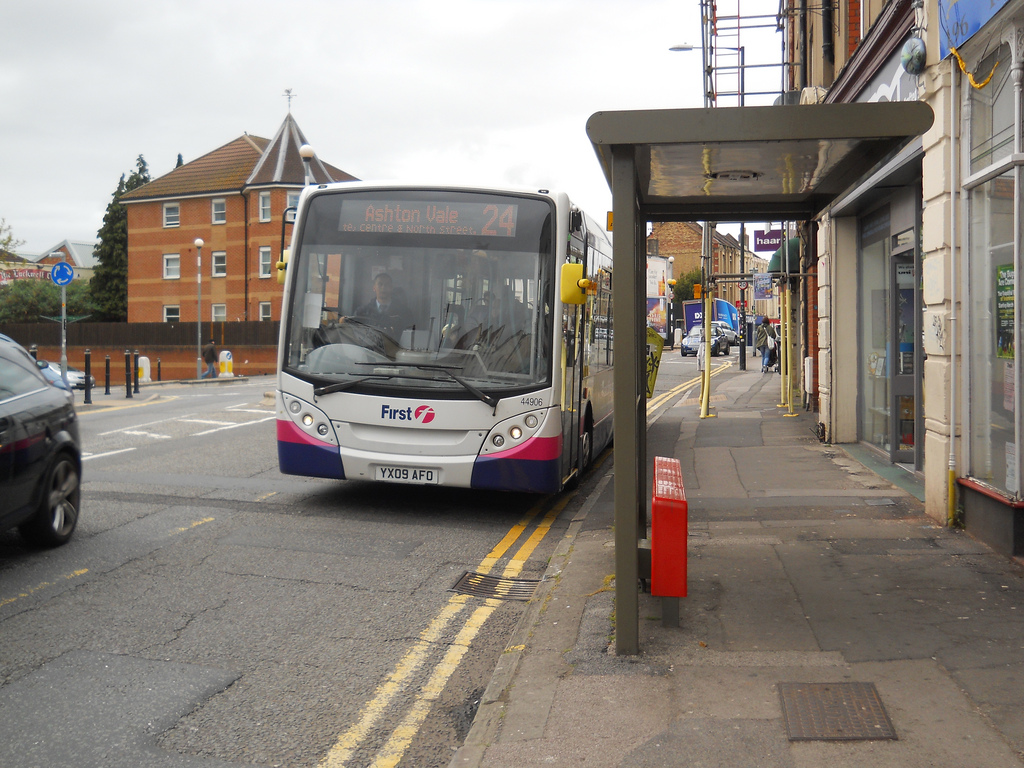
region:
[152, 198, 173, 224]
a window on a building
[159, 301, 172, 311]
a window on a building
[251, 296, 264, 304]
a window on a building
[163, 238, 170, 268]
a window on a building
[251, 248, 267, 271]
a window on a building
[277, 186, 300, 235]
a window on a building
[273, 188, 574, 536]
the front of a bus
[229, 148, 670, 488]
a large white bus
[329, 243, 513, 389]
the windshield of a bus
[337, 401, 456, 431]
the logo of a bus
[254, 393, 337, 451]
the right headlight of a bus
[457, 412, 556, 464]
the left headlight of a bus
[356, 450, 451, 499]
the license plate of a bus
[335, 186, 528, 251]
the sign on a bus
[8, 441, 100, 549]
the wheel of a car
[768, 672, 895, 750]
Sewer drain opening on the sidewalk.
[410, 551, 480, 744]
Two solid yellow lines on the ground.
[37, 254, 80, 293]
Blue sign on top of the pole.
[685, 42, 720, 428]
Yellow pole on the side of the building.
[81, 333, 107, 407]
Small black pole in the parking lot.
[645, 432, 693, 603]
Red banister on the side of bus stop.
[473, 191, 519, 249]
Orange numbers lit up in front of the bus.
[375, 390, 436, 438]
Word first painted on the front of the bus.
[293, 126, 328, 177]
White light on top of the building.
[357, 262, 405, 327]
Man driving the bus.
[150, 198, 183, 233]
a window on a building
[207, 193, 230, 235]
a window on a building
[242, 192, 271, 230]
a window on a building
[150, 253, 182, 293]
a window on a building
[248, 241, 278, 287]
a window on a building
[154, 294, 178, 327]
a window on a building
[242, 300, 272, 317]
a window on a building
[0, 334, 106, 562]
a car on a street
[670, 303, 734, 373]
a car on a street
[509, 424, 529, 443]
light on the front of the bus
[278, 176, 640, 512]
white bus on the roadway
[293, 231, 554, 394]
windshield of a white bus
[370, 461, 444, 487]
license plate of the white bus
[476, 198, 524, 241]
number 24 on the white bus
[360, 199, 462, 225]
destination of the white bus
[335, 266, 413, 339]
driver of the bus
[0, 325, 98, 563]
dark colored car on the road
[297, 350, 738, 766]
yellow double line on the road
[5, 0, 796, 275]
grey colored sky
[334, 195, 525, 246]
digital display on the bus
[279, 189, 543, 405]
window of the bus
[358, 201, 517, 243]
the text is yellow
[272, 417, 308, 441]
the paint is pink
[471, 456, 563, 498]
the paint is blue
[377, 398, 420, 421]
text on the bus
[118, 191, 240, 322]
the paint is orange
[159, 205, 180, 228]
window on the building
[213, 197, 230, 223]
window on the building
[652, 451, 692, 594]
the box is red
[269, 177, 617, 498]
the front of a bus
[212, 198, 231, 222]
a window of a building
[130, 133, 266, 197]
a roof of a building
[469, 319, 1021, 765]
a long sidewalk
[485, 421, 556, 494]
pink and purple stripes on bus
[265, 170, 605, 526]
Bus at a bus stop.